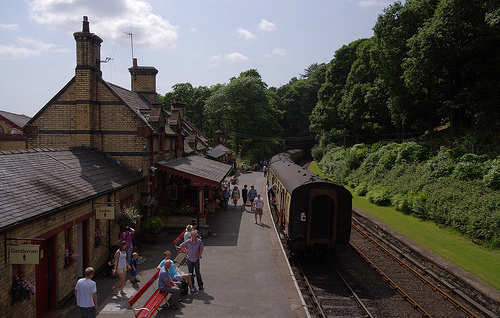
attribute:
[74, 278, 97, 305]
t-shirt — white 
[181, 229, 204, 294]
man — standing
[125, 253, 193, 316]
bench — red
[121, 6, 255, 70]
clouds — white 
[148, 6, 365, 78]
sky — blue 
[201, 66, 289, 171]
tree — leafy, big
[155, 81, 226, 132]
tree — leafy, big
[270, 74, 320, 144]
tree — leafy, big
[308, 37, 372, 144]
tree — leafy, big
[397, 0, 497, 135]
tree — leafy, big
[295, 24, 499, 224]
trees — leafy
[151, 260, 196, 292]
top — blue 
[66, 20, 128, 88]
chimney — brown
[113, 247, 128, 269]
tank top — white 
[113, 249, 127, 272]
top — white 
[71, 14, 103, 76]
tower — little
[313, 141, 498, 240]
bushes line — leafy